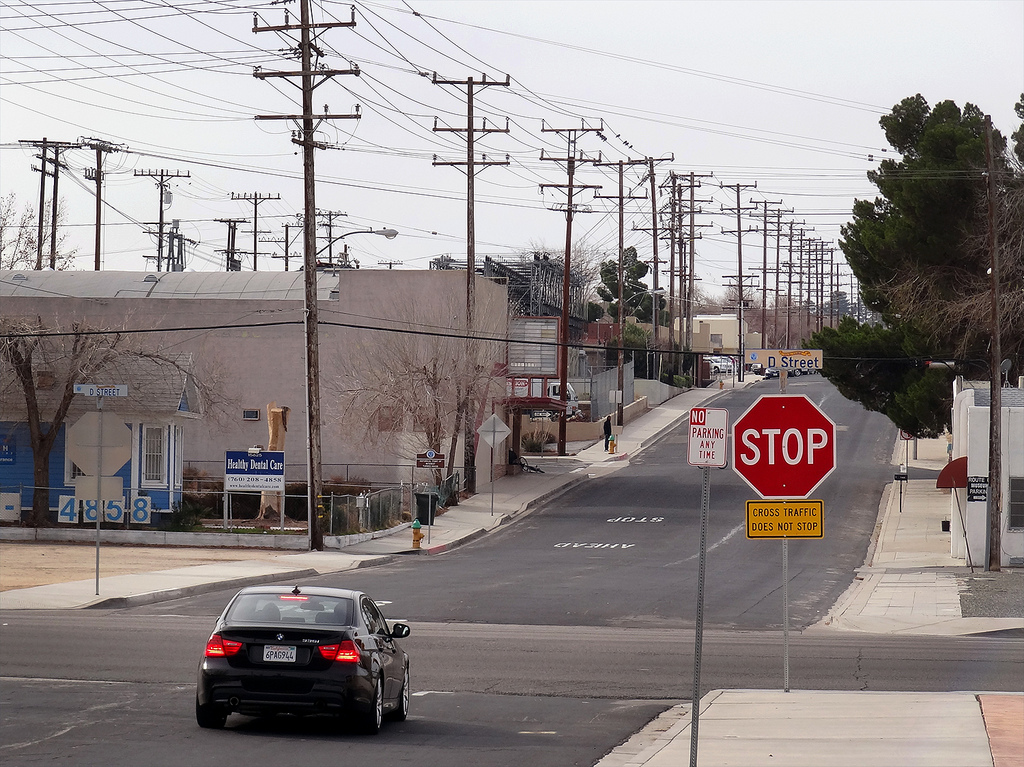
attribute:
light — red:
[309, 594, 394, 700]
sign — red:
[720, 402, 809, 517]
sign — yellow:
[719, 467, 882, 561]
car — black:
[123, 551, 437, 763]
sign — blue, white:
[214, 406, 308, 541]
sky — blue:
[603, 63, 699, 167]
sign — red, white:
[719, 376, 907, 524]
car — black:
[184, 534, 399, 727]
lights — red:
[169, 594, 451, 705]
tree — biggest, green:
[877, 179, 960, 368]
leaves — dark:
[882, 171, 963, 401]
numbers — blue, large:
[28, 453, 206, 549]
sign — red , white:
[741, 386, 869, 549]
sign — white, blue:
[223, 447, 349, 528]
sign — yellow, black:
[730, 492, 852, 547]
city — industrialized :
[1, 1, 1017, 749]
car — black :
[186, 571, 426, 753]